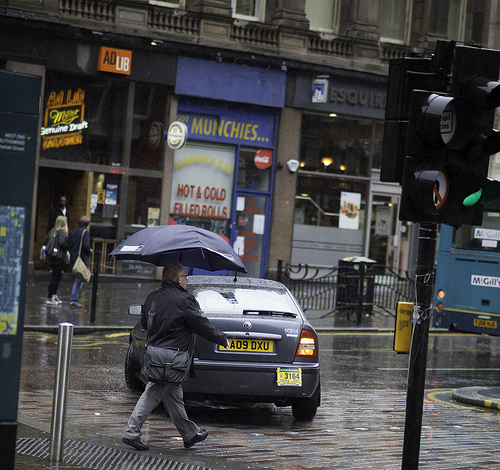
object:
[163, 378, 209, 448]
leg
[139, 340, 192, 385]
bag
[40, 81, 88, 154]
sign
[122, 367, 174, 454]
leg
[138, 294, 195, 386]
satchel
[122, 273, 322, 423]
car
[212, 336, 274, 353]
license plate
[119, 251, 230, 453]
man